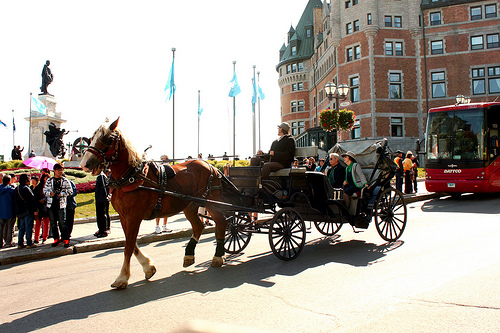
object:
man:
[42, 163, 73, 247]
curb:
[142, 154, 254, 163]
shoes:
[63, 240, 70, 248]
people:
[42, 163, 73, 248]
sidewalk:
[0, 181, 435, 266]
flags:
[31, 96, 48, 115]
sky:
[0, 0, 309, 159]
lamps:
[323, 81, 337, 94]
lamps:
[318, 109, 340, 132]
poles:
[335, 94, 339, 145]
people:
[256, 122, 296, 179]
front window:
[424, 105, 500, 169]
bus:
[425, 101, 500, 197]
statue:
[38, 60, 56, 98]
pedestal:
[24, 94, 68, 160]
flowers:
[318, 108, 358, 132]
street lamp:
[324, 80, 350, 142]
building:
[276, 0, 500, 168]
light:
[337, 82, 350, 95]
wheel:
[267, 208, 307, 261]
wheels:
[373, 188, 408, 242]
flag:
[164, 58, 177, 103]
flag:
[198, 99, 205, 119]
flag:
[228, 70, 241, 97]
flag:
[250, 76, 257, 115]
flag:
[258, 81, 266, 100]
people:
[341, 151, 370, 208]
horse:
[78, 115, 226, 288]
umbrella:
[22, 156, 58, 170]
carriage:
[223, 137, 399, 228]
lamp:
[323, 81, 350, 101]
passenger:
[323, 153, 344, 189]